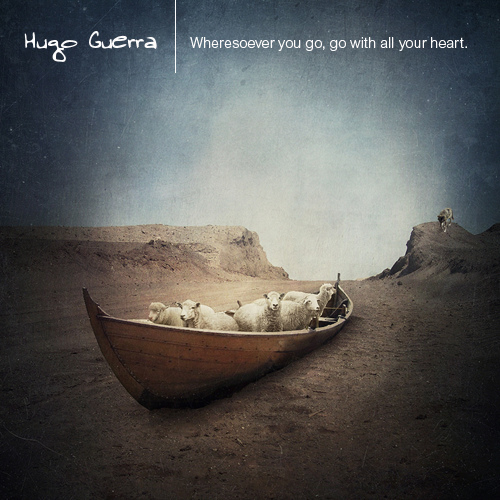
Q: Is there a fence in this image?
A: No, there are no fences.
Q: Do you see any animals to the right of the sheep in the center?
A: Yes, there is an animal to the right of the sheep.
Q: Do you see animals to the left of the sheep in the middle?
A: No, the animal is to the right of the sheep.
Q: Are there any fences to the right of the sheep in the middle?
A: No, there is an animal to the right of the sheep.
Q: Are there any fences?
A: No, there are no fences.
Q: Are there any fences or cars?
A: No, there are no fences or cars.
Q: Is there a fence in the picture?
A: No, there are no fences.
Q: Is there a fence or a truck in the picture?
A: No, there are no fences or trucks.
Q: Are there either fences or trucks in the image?
A: No, there are no fences or trucks.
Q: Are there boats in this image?
A: Yes, there is a boat.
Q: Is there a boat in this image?
A: Yes, there is a boat.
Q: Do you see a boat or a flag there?
A: Yes, there is a boat.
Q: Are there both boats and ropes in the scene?
A: No, there is a boat but no ropes.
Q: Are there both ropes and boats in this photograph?
A: No, there is a boat but no ropes.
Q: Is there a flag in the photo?
A: No, there are no flags.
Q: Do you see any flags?
A: No, there are no flags.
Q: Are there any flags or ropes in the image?
A: No, there are no flags or ropes.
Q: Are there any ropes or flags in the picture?
A: No, there are no flags or ropes.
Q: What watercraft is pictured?
A: The watercraft is a boat.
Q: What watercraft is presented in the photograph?
A: The watercraft is a boat.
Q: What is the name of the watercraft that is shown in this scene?
A: The watercraft is a boat.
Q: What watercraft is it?
A: The watercraft is a boat.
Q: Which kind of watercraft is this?
A: This is a boat.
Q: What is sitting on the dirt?
A: The boat is sitting on the dirt.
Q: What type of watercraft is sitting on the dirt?
A: The watercraft is a boat.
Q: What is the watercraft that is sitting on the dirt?
A: The watercraft is a boat.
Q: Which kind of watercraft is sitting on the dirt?
A: The watercraft is a boat.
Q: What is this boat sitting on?
A: The boat is sitting on the dirt.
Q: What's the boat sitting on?
A: The boat is sitting on the dirt.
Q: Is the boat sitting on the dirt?
A: Yes, the boat is sitting on the dirt.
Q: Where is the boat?
A: The boat is on the road.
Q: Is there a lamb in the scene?
A: Yes, there is a lamb.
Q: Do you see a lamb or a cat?
A: Yes, there is a lamb.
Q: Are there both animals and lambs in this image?
A: Yes, there are both a lamb and an animal.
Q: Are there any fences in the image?
A: No, there are no fences.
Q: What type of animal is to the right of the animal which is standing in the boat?
A: The animal is a lamb.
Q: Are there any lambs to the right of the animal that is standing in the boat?
A: Yes, there is a lamb to the right of the animal.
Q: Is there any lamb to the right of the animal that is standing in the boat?
A: Yes, there is a lamb to the right of the animal.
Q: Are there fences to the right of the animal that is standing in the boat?
A: No, there is a lamb to the right of the animal.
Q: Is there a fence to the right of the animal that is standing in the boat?
A: No, there is a lamb to the right of the animal.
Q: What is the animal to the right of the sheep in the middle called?
A: The animal is a lamb.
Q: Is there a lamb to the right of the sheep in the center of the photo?
A: Yes, there is a lamb to the right of the sheep.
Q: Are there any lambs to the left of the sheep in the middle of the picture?
A: No, the lamb is to the right of the sheep.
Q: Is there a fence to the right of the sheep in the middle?
A: No, there is a lamb to the right of the sheep.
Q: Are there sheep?
A: Yes, there is a sheep.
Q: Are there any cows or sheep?
A: Yes, there is a sheep.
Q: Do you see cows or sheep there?
A: Yes, there is a sheep.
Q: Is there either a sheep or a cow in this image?
A: Yes, there is a sheep.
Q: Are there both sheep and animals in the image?
A: Yes, there are both a sheep and animals.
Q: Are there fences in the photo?
A: No, there are no fences.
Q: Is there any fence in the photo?
A: No, there are no fences.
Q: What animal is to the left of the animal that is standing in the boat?
A: The animal is a sheep.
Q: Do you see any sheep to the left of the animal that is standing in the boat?
A: Yes, there is a sheep to the left of the animal.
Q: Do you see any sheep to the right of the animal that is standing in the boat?
A: No, the sheep is to the left of the animal.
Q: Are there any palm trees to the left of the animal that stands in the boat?
A: No, there is a sheep to the left of the animal.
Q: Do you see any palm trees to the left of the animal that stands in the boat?
A: No, there is a sheep to the left of the animal.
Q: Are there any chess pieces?
A: No, there are no chess pieces.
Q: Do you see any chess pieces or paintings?
A: No, there are no chess pieces or paintings.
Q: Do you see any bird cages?
A: No, there are no bird cages.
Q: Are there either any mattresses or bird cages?
A: No, there are no bird cages or mattresses.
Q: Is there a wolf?
A: Yes, there is a wolf.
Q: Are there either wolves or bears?
A: Yes, there is a wolf.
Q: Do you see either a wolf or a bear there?
A: Yes, there is a wolf.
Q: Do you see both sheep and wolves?
A: Yes, there are both a wolf and a sheep.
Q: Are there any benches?
A: No, there are no benches.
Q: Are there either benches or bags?
A: No, there are no benches or bags.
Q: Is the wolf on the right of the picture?
A: Yes, the wolf is on the right of the image.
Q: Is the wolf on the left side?
A: No, the wolf is on the right of the image.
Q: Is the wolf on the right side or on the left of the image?
A: The wolf is on the right of the image.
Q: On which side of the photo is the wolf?
A: The wolf is on the right of the image.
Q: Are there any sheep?
A: Yes, there is a sheep.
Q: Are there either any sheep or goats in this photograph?
A: Yes, there is a sheep.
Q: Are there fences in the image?
A: No, there are no fences.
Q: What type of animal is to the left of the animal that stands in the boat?
A: The animal is a sheep.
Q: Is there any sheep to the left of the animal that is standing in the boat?
A: Yes, there is a sheep to the left of the animal.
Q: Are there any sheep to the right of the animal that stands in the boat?
A: No, the sheep is to the left of the animal.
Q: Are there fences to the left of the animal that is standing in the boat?
A: No, there is a sheep to the left of the animal.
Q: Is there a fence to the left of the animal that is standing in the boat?
A: No, there is a sheep to the left of the animal.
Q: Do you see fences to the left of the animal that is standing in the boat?
A: No, there is a sheep to the left of the animal.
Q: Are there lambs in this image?
A: Yes, there is a lamb.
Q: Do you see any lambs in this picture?
A: Yes, there is a lamb.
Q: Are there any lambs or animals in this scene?
A: Yes, there is a lamb.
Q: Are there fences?
A: No, there are no fences.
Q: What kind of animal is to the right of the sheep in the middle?
A: The animal is a lamb.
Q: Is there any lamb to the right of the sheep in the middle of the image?
A: Yes, there is a lamb to the right of the sheep.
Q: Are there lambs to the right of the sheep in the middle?
A: Yes, there is a lamb to the right of the sheep.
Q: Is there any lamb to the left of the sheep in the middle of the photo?
A: No, the lamb is to the right of the sheep.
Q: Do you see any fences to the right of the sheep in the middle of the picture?
A: No, there is a lamb to the right of the sheep.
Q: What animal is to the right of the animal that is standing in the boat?
A: The animal is a lamb.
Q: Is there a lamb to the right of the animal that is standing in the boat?
A: Yes, there is a lamb to the right of the animal.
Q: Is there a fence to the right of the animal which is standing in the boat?
A: No, there is a lamb to the right of the animal.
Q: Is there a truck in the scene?
A: No, there are no trucks.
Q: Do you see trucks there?
A: No, there are no trucks.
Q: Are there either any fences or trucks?
A: No, there are no trucks or fences.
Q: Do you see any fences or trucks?
A: No, there are no trucks or fences.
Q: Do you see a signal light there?
A: No, there are no traffic lights.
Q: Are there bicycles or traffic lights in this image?
A: No, there are no traffic lights or bicycles.